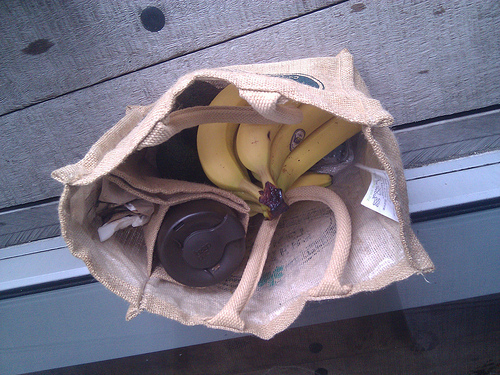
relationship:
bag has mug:
[67, 68, 464, 351] [148, 199, 251, 288]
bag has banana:
[43, 49, 436, 342] [198, 84, 261, 194]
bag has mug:
[43, 49, 436, 342] [148, 199, 251, 288]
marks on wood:
[139, 6, 166, 33] [32, 1, 276, 92]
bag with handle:
[43, 49, 436, 342] [206, 185, 353, 332]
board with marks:
[0, 1, 345, 116] [113, 6, 173, 41]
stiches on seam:
[128, 285, 147, 299] [107, 241, 158, 322]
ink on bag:
[263, 214, 334, 271] [43, 49, 436, 342]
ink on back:
[263, 214, 334, 271] [228, 62, 351, 86]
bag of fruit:
[43, 49, 436, 342] [195, 84, 361, 220]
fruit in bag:
[195, 84, 361, 220] [43, 49, 436, 342]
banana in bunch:
[295, 120, 345, 174] [182, 98, 350, 208]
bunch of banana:
[182, 98, 350, 208] [295, 120, 345, 174]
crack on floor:
[1, 5, 381, 121] [5, 2, 499, 196]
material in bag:
[93, 205, 160, 250] [90, 175, 157, 247]